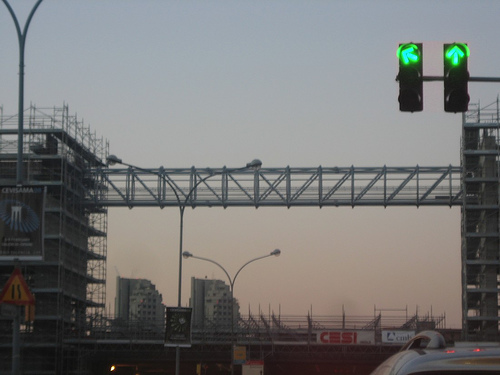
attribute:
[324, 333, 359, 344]
letters — red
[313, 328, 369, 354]
sign — white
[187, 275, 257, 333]
building — identical, similar, tall, background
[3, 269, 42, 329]
sign — triangular shaped, caution, yellow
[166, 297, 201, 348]
sign — black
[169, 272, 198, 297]
pole — tall, metal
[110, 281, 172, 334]
building — identical, similar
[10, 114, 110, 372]
building — under construction, tall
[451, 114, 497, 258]
building — under construction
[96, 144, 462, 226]
walkway — mid buildings, over street, between buildings, connecting buildings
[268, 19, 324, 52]
sky — clear, dim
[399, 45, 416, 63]
green arrow — light, pointing left, facing left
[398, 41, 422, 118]
light — green, traffic, hanging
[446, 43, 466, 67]
green arrow — light, pointing straight, facing straight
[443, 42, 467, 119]
light — green, traffic, hanging